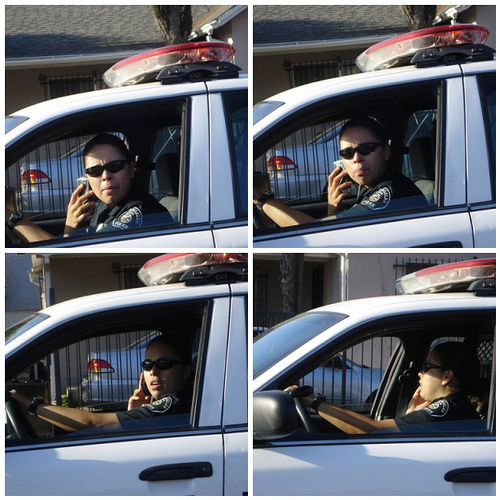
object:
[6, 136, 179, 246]
cop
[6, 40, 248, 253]
car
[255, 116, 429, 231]
officer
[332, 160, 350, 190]
phone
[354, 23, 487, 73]
lighs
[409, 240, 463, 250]
handle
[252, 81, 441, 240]
window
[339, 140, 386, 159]
sunglasses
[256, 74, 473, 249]
door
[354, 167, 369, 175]
teeth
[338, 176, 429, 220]
uniform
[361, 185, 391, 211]
patch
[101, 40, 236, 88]
light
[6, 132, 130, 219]
gate